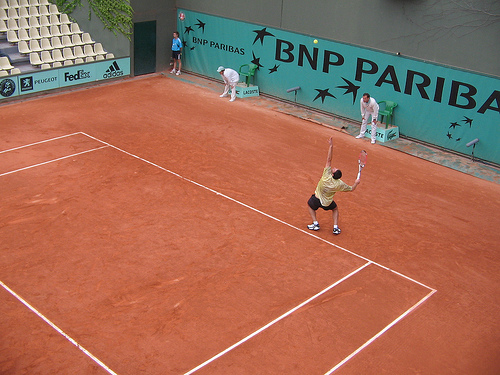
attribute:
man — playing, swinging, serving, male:
[299, 120, 370, 241]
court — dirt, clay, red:
[109, 85, 316, 225]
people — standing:
[170, 30, 392, 139]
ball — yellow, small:
[304, 34, 321, 45]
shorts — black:
[309, 191, 336, 214]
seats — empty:
[3, 7, 89, 53]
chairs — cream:
[33, 39, 97, 60]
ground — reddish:
[124, 98, 165, 137]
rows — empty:
[24, 38, 62, 62]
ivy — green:
[89, 4, 131, 24]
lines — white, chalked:
[59, 124, 103, 159]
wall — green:
[246, 13, 361, 116]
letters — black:
[272, 44, 345, 70]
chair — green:
[239, 65, 265, 84]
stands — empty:
[0, 6, 126, 83]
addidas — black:
[98, 58, 126, 84]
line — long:
[135, 146, 309, 247]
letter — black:
[323, 48, 342, 77]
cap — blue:
[216, 67, 226, 71]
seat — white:
[31, 47, 39, 67]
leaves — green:
[113, 16, 125, 42]